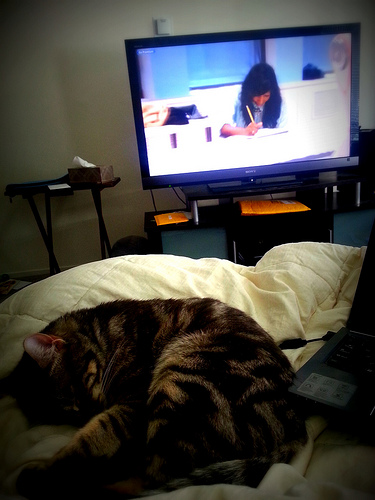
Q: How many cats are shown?
A: One.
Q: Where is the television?
A: Background.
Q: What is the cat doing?
A: Sleeping.